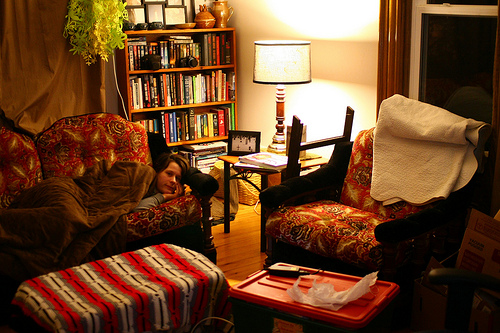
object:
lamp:
[254, 39, 311, 154]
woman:
[0, 154, 194, 279]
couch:
[3, 112, 218, 307]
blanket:
[370, 93, 487, 205]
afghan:
[11, 242, 233, 332]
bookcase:
[116, 26, 238, 173]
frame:
[227, 130, 260, 157]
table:
[213, 150, 333, 254]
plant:
[62, 0, 131, 65]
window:
[419, 13, 497, 125]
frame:
[378, 0, 499, 148]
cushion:
[263, 126, 429, 267]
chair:
[260, 126, 467, 332]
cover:
[1, 160, 156, 316]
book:
[209, 70, 216, 103]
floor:
[211, 201, 264, 289]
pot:
[195, 4, 215, 29]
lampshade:
[254, 40, 310, 85]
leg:
[223, 160, 230, 232]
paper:
[284, 268, 383, 312]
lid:
[230, 262, 400, 328]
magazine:
[239, 149, 301, 169]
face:
[154, 161, 181, 195]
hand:
[161, 185, 184, 201]